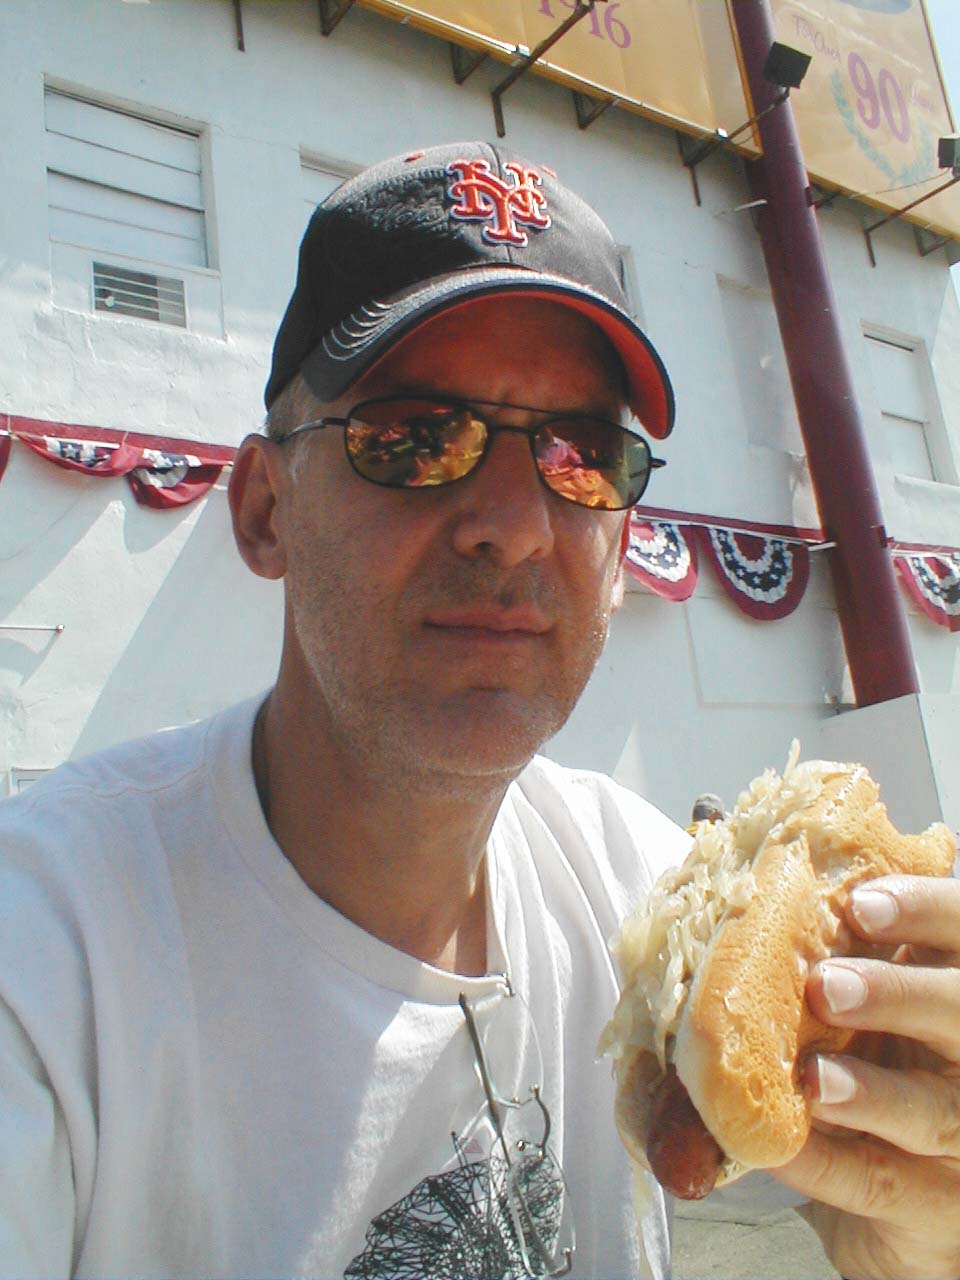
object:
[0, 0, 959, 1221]
wall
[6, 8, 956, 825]
building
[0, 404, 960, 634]
patriotic bunting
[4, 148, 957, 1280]
man